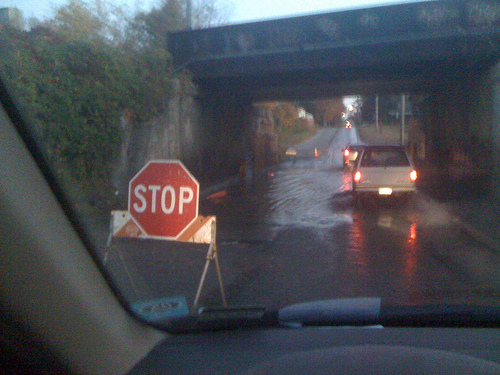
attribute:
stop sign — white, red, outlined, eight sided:
[125, 159, 201, 241]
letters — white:
[133, 185, 194, 217]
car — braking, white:
[350, 145, 418, 205]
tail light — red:
[410, 169, 418, 183]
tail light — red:
[352, 170, 360, 184]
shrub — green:
[5, 24, 201, 216]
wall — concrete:
[39, 75, 287, 209]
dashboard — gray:
[112, 325, 499, 373]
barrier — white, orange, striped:
[104, 211, 229, 311]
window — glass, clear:
[0, 1, 499, 330]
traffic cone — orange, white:
[312, 147, 319, 152]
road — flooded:
[88, 124, 500, 308]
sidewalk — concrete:
[416, 168, 500, 243]